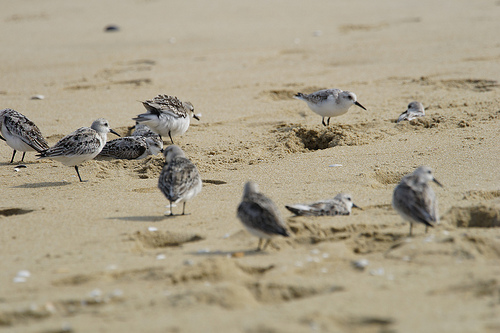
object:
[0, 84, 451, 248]
group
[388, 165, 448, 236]
birds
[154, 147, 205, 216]
bird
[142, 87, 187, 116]
feathers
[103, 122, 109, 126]
eye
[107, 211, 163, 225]
shadow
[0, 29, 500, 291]
ground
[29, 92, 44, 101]
rock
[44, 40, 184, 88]
sand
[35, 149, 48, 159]
feathers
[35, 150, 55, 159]
tail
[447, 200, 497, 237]
whole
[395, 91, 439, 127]
seashell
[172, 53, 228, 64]
part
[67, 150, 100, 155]
edge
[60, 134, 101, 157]
wing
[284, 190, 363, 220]
bird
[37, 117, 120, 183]
bird